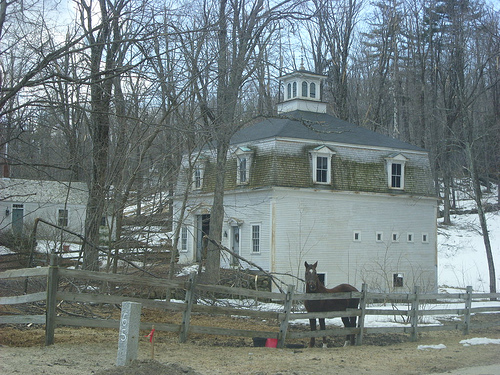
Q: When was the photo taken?
A: Daytime.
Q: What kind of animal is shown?
A: Horse.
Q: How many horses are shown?
A: One.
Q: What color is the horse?
A: Brown.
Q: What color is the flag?
A: Red.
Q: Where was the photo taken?
A: Ranch.